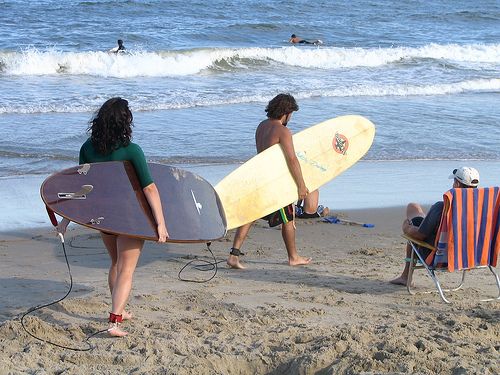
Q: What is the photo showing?
A: It is showing a beach.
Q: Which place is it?
A: It is a beach.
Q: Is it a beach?
A: Yes, it is a beach.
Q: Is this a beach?
A: Yes, it is a beach.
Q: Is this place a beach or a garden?
A: It is a beach.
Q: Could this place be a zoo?
A: No, it is a beach.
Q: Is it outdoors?
A: Yes, it is outdoors.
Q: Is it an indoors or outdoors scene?
A: It is outdoors.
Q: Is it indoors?
A: No, it is outdoors.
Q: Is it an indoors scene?
A: No, it is outdoors.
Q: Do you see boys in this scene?
A: No, there are no boys.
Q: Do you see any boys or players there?
A: No, there are no boys or players.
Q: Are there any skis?
A: No, there are no skis.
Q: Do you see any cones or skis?
A: No, there are no skis or cones.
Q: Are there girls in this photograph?
A: No, there are no girls.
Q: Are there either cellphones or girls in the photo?
A: No, there are no girls or cellphones.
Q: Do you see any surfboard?
A: Yes, there is a surfboard.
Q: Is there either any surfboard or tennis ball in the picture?
A: Yes, there is a surfboard.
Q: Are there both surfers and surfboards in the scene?
A: Yes, there are both a surfboard and a surfer.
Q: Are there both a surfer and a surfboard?
A: Yes, there are both a surfboard and a surfer.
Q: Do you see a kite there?
A: No, there are no kites.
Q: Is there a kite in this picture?
A: No, there are no kites.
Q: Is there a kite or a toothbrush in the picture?
A: No, there are no kites or toothbrushes.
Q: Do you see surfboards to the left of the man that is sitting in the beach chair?
A: Yes, there is a surfboard to the left of the man.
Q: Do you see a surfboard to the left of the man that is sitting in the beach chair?
A: Yes, there is a surfboard to the left of the man.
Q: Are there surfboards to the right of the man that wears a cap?
A: No, the surfboard is to the left of the man.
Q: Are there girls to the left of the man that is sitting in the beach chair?
A: No, there is a surfboard to the left of the man.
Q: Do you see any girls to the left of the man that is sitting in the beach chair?
A: No, there is a surfboard to the left of the man.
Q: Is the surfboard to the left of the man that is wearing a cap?
A: Yes, the surfboard is to the left of the man.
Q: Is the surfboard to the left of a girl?
A: No, the surfboard is to the left of the man.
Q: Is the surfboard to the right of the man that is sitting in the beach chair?
A: No, the surfboard is to the left of the man.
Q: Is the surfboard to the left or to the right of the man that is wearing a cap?
A: The surfboard is to the left of the man.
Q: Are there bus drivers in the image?
A: No, there are no bus drivers.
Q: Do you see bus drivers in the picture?
A: No, there are no bus drivers.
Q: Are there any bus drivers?
A: No, there are no bus drivers.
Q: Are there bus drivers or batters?
A: No, there are no bus drivers or batters.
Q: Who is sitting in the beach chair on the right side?
A: The man is sitting in the beach chair.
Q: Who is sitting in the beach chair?
A: The man is sitting in the beach chair.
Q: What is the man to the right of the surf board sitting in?
A: The man is sitting in the beach chair.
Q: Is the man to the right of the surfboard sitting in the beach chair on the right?
A: Yes, the man is sitting in the beach chair.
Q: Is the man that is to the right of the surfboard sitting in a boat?
A: No, the man is sitting in the beach chair.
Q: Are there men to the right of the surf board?
A: Yes, there is a man to the right of the surf board.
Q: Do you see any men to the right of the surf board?
A: Yes, there is a man to the right of the surf board.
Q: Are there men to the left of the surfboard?
A: No, the man is to the right of the surfboard.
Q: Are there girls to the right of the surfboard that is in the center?
A: No, there is a man to the right of the surfboard.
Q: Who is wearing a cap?
A: The man is wearing a cap.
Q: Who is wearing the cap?
A: The man is wearing a cap.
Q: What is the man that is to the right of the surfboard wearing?
A: The man is wearing a cap.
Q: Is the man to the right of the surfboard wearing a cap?
A: Yes, the man is wearing a cap.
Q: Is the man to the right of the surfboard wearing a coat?
A: No, the man is wearing a cap.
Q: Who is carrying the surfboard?
A: The man is carrying the surfboard.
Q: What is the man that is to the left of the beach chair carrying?
A: The man is carrying a surf board.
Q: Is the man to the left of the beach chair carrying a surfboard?
A: Yes, the man is carrying a surfboard.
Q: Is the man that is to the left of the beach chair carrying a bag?
A: No, the man is carrying a surfboard.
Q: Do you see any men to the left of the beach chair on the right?
A: Yes, there is a man to the left of the beach chair.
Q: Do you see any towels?
A: Yes, there is a towel.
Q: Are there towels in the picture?
A: Yes, there is a towel.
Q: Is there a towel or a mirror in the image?
A: Yes, there is a towel.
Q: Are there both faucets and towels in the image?
A: No, there is a towel but no faucets.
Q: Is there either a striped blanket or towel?
A: Yes, there is a striped towel.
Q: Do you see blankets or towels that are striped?
A: Yes, the towel is striped.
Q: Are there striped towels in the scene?
A: Yes, there is a striped towel.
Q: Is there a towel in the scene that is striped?
A: Yes, there is a towel that is striped.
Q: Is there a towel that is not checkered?
A: Yes, there is a striped towel.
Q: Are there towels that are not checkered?
A: Yes, there is a striped towel.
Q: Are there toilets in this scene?
A: No, there are no toilets.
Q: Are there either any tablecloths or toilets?
A: No, there are no toilets or tablecloths.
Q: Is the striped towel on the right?
A: Yes, the towel is on the right of the image.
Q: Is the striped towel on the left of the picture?
A: No, the towel is on the right of the image.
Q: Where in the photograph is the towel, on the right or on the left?
A: The towel is on the right of the image.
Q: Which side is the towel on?
A: The towel is on the right of the image.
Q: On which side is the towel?
A: The towel is on the right of the image.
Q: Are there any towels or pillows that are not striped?
A: No, there is a towel but it is striped.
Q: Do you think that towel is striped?
A: Yes, the towel is striped.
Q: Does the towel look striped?
A: Yes, the towel is striped.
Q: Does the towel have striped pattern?
A: Yes, the towel is striped.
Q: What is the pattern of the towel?
A: The towel is striped.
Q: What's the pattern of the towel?
A: The towel is striped.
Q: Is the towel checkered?
A: No, the towel is striped.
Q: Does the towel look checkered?
A: No, the towel is striped.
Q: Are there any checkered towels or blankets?
A: No, there is a towel but it is striped.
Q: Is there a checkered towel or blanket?
A: No, there is a towel but it is striped.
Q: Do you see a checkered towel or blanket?
A: No, there is a towel but it is striped.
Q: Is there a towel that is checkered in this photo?
A: No, there is a towel but it is striped.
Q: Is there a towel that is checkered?
A: No, there is a towel but it is striped.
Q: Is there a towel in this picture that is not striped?
A: No, there is a towel but it is striped.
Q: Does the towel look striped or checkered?
A: The towel is striped.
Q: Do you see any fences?
A: No, there are no fences.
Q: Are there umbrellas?
A: No, there are no umbrellas.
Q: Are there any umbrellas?
A: No, there are no umbrellas.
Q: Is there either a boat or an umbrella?
A: No, there are no umbrellas or boats.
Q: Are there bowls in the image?
A: No, there are no bowls.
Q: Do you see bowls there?
A: No, there are no bowls.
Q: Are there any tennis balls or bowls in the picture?
A: No, there are no bowls or tennis balls.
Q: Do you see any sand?
A: Yes, there is sand.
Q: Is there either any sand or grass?
A: Yes, there is sand.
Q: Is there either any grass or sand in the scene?
A: Yes, there is sand.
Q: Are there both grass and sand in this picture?
A: No, there is sand but no grass.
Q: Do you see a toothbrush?
A: No, there are no toothbrushes.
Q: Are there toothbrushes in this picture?
A: No, there are no toothbrushes.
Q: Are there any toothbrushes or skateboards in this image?
A: No, there are no toothbrushes or skateboards.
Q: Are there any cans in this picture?
A: No, there are no cans.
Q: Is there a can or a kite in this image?
A: No, there are no cans or kites.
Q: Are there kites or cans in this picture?
A: No, there are no cans or kites.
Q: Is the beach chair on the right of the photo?
A: Yes, the beach chair is on the right of the image.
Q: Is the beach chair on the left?
A: No, the beach chair is on the right of the image.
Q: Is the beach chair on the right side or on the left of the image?
A: The beach chair is on the right of the image.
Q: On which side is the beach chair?
A: The beach chair is on the right of the image.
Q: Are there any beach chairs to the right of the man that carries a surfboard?
A: Yes, there is a beach chair to the right of the man.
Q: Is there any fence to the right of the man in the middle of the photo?
A: No, there is a beach chair to the right of the man.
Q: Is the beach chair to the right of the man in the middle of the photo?
A: Yes, the beach chair is to the right of the man.